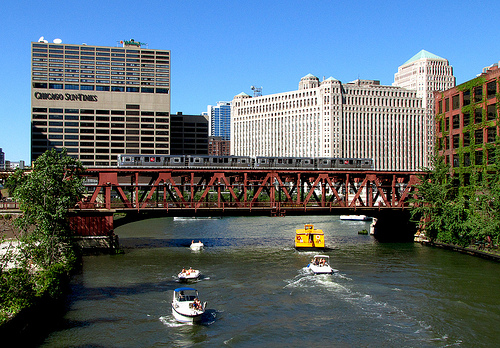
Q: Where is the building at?
A: By the water.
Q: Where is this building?
A: By the water.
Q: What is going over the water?
A: A bridge.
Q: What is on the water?
A: There are bots on the water.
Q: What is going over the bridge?
A: Train.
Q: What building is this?
A: Chicago Sun Times building.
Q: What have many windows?
A: The white building.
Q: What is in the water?
A: Five boats.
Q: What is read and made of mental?
A: Bridge.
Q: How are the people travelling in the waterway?
A: By boat.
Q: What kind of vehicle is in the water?
A: Boat.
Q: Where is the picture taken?
A: Large city.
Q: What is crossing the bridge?
A: Train.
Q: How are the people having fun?
A: Boating.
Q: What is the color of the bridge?
A: Brown.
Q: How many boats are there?
A: 5.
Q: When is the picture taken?
A: Daytime.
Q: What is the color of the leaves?
A: Green.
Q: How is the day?
A: Sunny.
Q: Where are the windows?
A: In the building wall.